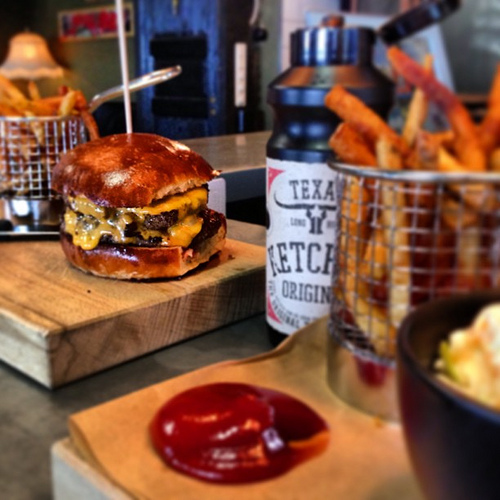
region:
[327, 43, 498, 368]
Container of fries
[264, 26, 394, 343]
Bottle of ketchup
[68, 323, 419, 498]
Paper bag with a pile of ketchup on it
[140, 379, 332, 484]
Pile of ketchup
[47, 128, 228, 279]
Hamburger next to a container of fries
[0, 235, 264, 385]
Wooden board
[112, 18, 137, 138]
Stick used to hold the contents of the hamburger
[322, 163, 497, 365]
Metal container used to hold the fries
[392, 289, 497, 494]
Large navy blue bowl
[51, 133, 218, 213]
Top bun of the hamburger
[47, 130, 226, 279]
a small, sloppy cheeseburge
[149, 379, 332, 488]
a puddle of red ketchup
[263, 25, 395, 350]
a bottle of ketchup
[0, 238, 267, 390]
a wooden cutting board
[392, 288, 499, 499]
a smooth black bowl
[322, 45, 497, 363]
a wire basket of french fries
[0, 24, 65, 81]
a lampshade with light glowing inside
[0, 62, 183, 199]
a silver metal wire basket of fries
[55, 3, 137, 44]
a colorful hanging picture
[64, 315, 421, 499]
a brown piece of paper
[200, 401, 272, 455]
the ketchup is red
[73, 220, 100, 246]
the cheese is yellow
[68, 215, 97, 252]
the chesse is melty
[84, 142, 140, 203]
the bun is brown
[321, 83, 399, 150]
the fries are crispy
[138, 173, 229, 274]
the burger has a bite in it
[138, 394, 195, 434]
the ketchup is on the bag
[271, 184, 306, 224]
the lable is white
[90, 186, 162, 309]
the burger is sitting on the board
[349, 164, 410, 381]
the container is silver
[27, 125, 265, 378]
a sandwich on a board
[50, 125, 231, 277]
sandwich has melted cheese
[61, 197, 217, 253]
yellow melted cheeses in a sandwich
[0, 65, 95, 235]
a french fries on a basket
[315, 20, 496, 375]
french fries in a basket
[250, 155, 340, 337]
a white label on a bottle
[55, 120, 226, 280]
a cheeseburger on a wood board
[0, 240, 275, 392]
a wood board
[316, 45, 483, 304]
long slices of french fries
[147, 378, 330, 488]
The ketchup is red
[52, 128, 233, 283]
A burger with cheese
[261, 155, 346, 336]
Label on a bottle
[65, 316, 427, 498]
A brown paper bag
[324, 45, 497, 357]
A basket of french fries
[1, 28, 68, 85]
A light under lampshade is turned on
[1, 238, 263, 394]
A brown wooden board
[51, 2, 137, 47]
A painting on the wall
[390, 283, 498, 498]
A bowl with food in it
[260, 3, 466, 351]
A bottle is open